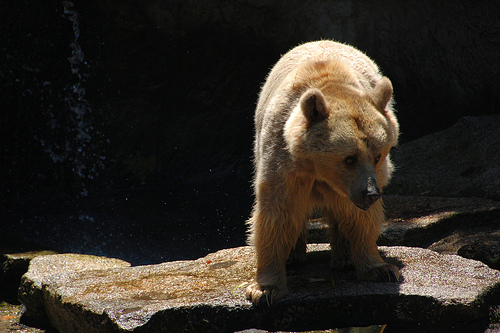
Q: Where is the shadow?
A: Beneath the bear.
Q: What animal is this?
A: Bear.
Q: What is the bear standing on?
A: Rock.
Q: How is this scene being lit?
A: Sunshine.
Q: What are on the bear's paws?
A: Claws.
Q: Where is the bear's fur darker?
A: The top.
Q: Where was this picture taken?
A: Zoo.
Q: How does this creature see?
A: Eyes.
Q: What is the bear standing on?
A: Rock.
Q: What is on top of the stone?
A: A bear.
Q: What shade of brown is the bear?
A: Light brown.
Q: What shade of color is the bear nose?
A: Black.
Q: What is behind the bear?
A: Rock wall.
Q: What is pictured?
A: Bear standing on a stone.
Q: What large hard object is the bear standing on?
A: Rock.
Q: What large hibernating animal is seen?
A: Bear.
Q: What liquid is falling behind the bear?
A: Water.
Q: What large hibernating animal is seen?
A: Bear.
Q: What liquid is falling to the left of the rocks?
A: Water.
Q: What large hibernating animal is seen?
A: Bear.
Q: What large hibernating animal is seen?
A: Bear.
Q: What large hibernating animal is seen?
A: Bear.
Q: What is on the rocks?
A: A bear.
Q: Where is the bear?
A: Standing on the rocks.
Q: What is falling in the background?
A: Water.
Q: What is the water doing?
A: Falling.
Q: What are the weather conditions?
A: Sunny.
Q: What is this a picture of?
A: A bear.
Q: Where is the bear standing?
A: On a rock.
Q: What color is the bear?
A: Brown.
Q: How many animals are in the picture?
A: One.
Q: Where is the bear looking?
A: To the right.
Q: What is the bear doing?
A: Standing on a rock.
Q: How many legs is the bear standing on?
A: Four.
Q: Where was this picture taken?
A: In a zoo.